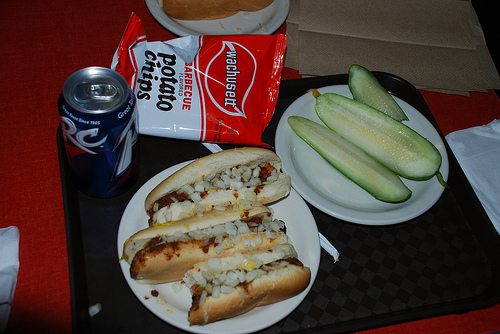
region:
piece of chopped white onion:
[213, 242, 225, 253]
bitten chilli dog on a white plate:
[182, 242, 317, 327]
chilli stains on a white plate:
[139, 289, 176, 315]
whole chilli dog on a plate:
[124, 203, 291, 283]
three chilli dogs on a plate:
[117, 145, 312, 325]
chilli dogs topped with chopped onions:
[112, 142, 322, 327]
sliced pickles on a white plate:
[273, 61, 457, 230]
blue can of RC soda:
[57, 62, 144, 182]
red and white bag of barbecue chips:
[109, 11, 291, 147]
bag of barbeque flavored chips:
[109, 10, 289, 147]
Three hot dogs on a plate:
[109, 143, 323, 332]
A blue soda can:
[56, 62, 142, 204]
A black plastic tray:
[51, 68, 497, 330]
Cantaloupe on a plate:
[274, 61, 451, 227]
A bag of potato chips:
[107, 10, 290, 150]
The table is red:
[1, 0, 498, 332]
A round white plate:
[275, 82, 450, 226]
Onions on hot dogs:
[157, 161, 295, 304]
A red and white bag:
[109, 9, 289, 150]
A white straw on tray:
[199, 136, 343, 265]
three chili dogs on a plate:
[117, 150, 324, 325]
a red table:
[0, 3, 498, 327]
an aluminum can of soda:
[59, 68, 137, 195]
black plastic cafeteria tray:
[55, 74, 499, 327]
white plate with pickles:
[280, 80, 451, 225]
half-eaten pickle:
[345, 64, 408, 119]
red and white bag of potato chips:
[106, 18, 287, 150]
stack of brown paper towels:
[290, 4, 498, 91]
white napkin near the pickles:
[455, 128, 498, 240]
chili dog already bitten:
[183, 247, 312, 323]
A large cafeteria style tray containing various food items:
[34, 15, 499, 332]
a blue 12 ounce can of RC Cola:
[48, 63, 143, 193]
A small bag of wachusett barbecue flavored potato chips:
[120, 25, 281, 144]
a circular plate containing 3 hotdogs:
[116, 148, 324, 332]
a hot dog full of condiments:
[144, 146, 289, 219]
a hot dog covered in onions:
[125, 210, 311, 270]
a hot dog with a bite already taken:
[178, 250, 322, 330]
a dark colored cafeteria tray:
[341, 238, 497, 315]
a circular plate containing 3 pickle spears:
[268, 63, 465, 223]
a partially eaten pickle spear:
[342, 62, 407, 125]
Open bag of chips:
[102, 11, 294, 151]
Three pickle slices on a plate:
[289, 65, 464, 220]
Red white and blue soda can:
[43, 61, 150, 198]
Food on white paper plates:
[110, 63, 457, 332]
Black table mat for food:
[51, 73, 493, 332]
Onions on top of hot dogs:
[148, 154, 293, 307]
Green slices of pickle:
[286, 52, 457, 219]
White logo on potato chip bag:
[216, 38, 246, 135]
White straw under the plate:
[190, 133, 358, 266]